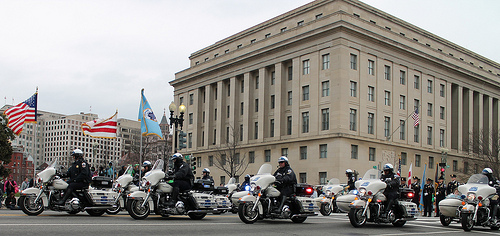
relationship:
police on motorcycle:
[269, 155, 298, 214] [235, 157, 305, 226]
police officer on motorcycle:
[366, 164, 404, 222] [346, 160, 416, 229]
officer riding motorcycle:
[56, 147, 95, 211] [17, 157, 116, 217]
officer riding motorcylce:
[165, 153, 201, 203] [106, 160, 151, 216]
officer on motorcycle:
[163, 153, 202, 207] [125, 159, 218, 219]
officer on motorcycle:
[52, 148, 94, 206] [16, 156, 123, 217]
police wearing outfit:
[262, 155, 298, 215] [266, 168, 295, 213]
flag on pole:
[1, 93, 35, 136] [30, 83, 40, 183]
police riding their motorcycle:
[269, 155, 298, 214] [230, 164, 322, 224]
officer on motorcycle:
[52, 148, 94, 206] [23, 167, 118, 213]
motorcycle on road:
[23, 167, 118, 213] [8, 225, 490, 235]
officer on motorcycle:
[163, 153, 202, 207] [125, 157, 215, 232]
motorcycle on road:
[125, 157, 215, 232] [2, 210, 498, 233]